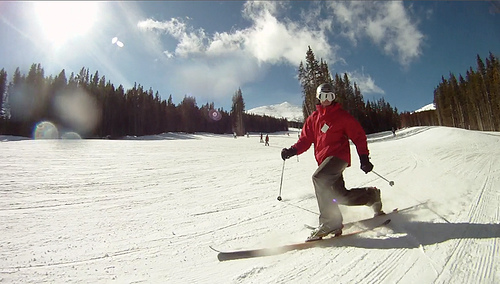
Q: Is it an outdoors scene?
A: Yes, it is outdoors.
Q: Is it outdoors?
A: Yes, it is outdoors.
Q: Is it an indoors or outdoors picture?
A: It is outdoors.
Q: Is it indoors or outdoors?
A: It is outdoors.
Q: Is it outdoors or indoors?
A: It is outdoors.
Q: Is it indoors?
A: No, it is outdoors.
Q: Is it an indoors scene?
A: No, it is outdoors.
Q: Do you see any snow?
A: Yes, there is snow.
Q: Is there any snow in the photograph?
A: Yes, there is snow.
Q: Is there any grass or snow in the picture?
A: Yes, there is snow.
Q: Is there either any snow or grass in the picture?
A: Yes, there is snow.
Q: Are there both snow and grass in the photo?
A: No, there is snow but no grass.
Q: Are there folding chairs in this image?
A: No, there are no folding chairs.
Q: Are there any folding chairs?
A: No, there are no folding chairs.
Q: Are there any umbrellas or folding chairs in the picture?
A: No, there are no folding chairs or umbrellas.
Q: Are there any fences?
A: No, there are no fences.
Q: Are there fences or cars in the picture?
A: No, there are no fences or cars.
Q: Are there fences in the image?
A: No, there are no fences.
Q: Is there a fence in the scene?
A: No, there are no fences.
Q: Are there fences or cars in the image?
A: No, there are no fences or cars.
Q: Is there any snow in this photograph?
A: Yes, there is snow.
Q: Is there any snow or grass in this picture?
A: Yes, there is snow.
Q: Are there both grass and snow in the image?
A: No, there is snow but no grass.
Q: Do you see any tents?
A: No, there are no tents.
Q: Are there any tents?
A: No, there are no tents.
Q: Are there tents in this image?
A: No, there are no tents.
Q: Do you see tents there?
A: No, there are no tents.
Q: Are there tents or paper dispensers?
A: No, there are no tents or paper dispensers.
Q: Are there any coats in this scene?
A: Yes, there is a coat.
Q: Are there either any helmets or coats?
A: Yes, there is a coat.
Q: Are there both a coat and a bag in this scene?
A: No, there is a coat but no bags.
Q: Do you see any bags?
A: No, there are no bags.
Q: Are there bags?
A: No, there are no bags.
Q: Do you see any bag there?
A: No, there are no bags.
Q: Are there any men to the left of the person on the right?
A: Yes, there is a man to the left of the person.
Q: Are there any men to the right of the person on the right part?
A: No, the man is to the left of the person.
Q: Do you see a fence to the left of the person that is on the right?
A: No, there is a man to the left of the person.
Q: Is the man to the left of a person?
A: Yes, the man is to the left of a person.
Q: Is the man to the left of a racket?
A: No, the man is to the left of a person.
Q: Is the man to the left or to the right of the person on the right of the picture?
A: The man is to the left of the person.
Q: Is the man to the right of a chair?
A: No, the man is to the right of a person.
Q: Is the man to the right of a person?
A: Yes, the man is to the right of a person.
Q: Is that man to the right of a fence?
A: No, the man is to the right of a person.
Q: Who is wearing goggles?
A: The man is wearing goggles.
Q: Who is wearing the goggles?
A: The man is wearing goggles.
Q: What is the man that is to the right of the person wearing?
A: The man is wearing goggles.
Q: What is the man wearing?
A: The man is wearing goggles.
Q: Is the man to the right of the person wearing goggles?
A: Yes, the man is wearing goggles.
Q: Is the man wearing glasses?
A: No, the man is wearing goggles.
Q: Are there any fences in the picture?
A: No, there are no fences.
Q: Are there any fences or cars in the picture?
A: No, there are no fences or cars.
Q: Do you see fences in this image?
A: No, there are no fences.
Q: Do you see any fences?
A: No, there are no fences.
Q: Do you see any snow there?
A: Yes, there is snow.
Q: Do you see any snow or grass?
A: Yes, there is snow.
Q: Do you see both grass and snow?
A: No, there is snow but no grass.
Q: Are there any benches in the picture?
A: No, there are no benches.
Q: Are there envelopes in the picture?
A: No, there are no envelopes.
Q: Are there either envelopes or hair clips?
A: No, there are no envelopes or hair clips.